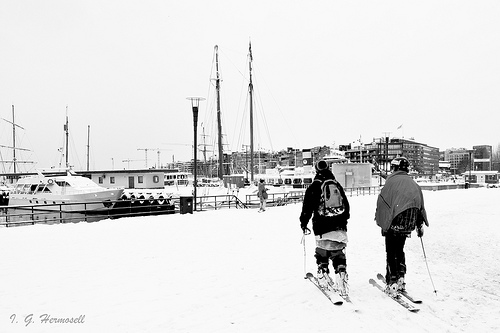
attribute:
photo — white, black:
[11, 17, 375, 322]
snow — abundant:
[231, 274, 281, 306]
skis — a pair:
[305, 272, 344, 307]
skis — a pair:
[337, 286, 362, 313]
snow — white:
[145, 219, 272, 309]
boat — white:
[2, 175, 125, 221]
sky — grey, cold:
[263, 3, 498, 113]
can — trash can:
[180, 194, 194, 211]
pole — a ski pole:
[289, 222, 317, 272]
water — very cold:
[3, 204, 95, 223]